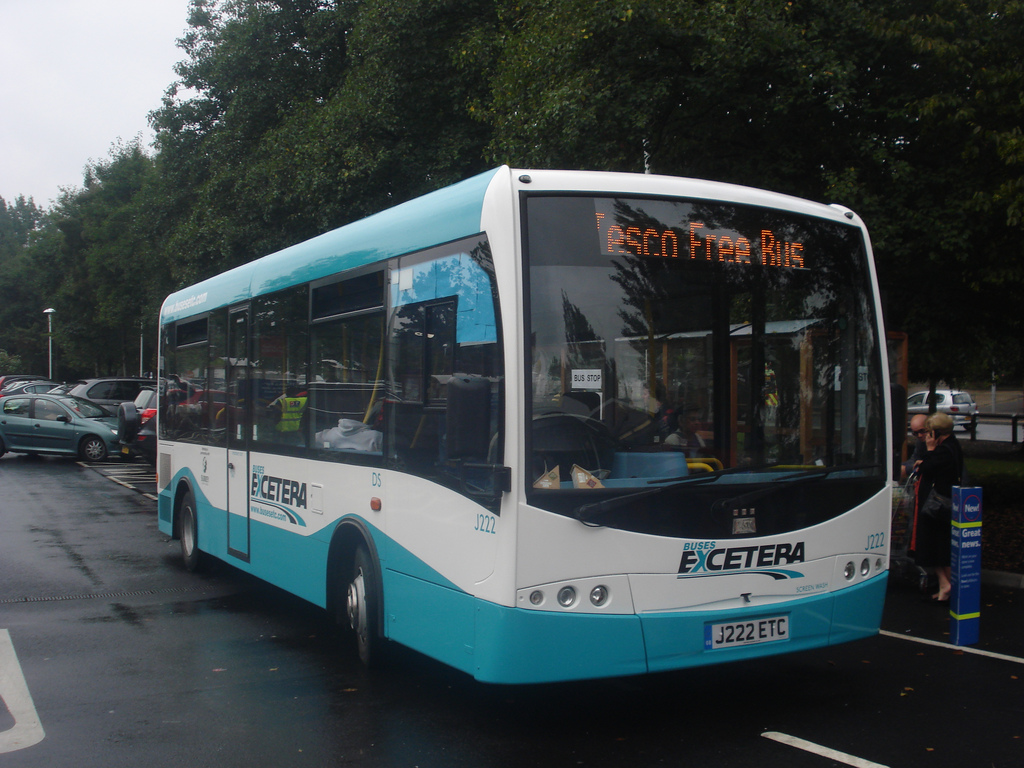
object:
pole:
[952, 484, 985, 644]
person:
[269, 384, 310, 447]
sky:
[0, 1, 203, 216]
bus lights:
[529, 558, 884, 608]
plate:
[700, 614, 793, 653]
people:
[911, 406, 962, 605]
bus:
[151, 165, 895, 686]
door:
[206, 297, 263, 574]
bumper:
[466, 578, 911, 686]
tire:
[176, 487, 198, 573]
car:
[0, 392, 122, 464]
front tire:
[329, 540, 389, 674]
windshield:
[521, 192, 883, 493]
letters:
[593, 213, 807, 271]